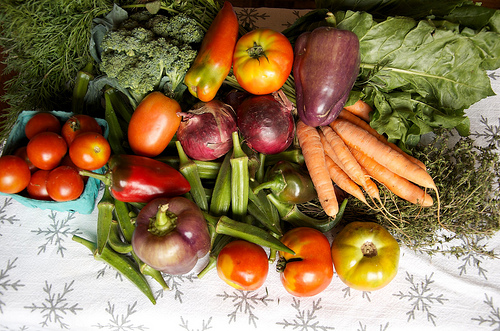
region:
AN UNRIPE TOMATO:
[328, 216, 408, 298]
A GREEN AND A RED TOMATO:
[270, 217, 410, 302]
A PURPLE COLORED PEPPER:
[123, 188, 221, 283]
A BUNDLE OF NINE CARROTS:
[286, 84, 459, 250]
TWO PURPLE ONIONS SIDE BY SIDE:
[166, 87, 306, 166]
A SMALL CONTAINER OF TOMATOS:
[0, 103, 115, 220]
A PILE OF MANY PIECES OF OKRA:
[63, 75, 373, 310]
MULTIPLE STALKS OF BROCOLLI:
[93, 2, 215, 123]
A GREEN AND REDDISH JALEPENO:
[248, 152, 338, 207]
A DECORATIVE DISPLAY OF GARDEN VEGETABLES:
[0, 0, 497, 309]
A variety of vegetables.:
[97, 80, 373, 260]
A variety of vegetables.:
[164, 104, 319, 227]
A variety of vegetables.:
[144, 132, 344, 274]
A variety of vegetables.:
[133, 121, 415, 326]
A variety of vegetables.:
[173, 68, 378, 208]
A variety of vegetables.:
[186, 179, 413, 301]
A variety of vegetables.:
[153, 61, 289, 166]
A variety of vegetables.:
[183, 11, 383, 138]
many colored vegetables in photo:
[14, 10, 456, 328]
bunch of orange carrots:
[294, 128, 434, 216]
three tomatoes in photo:
[224, 212, 405, 306]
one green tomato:
[344, 204, 434, 304]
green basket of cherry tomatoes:
[2, 98, 129, 233]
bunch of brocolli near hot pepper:
[88, 7, 243, 135]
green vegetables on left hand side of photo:
[20, 7, 204, 115]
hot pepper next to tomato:
[182, 7, 303, 111]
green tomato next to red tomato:
[270, 221, 424, 299]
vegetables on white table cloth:
[12, 12, 496, 304]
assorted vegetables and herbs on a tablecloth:
[21, 30, 471, 318]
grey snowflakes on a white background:
[21, 266, 282, 326]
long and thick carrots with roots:
[301, 130, 446, 225]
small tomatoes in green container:
[2, 86, 103, 221]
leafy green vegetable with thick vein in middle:
[367, 16, 488, 136]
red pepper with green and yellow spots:
[176, 15, 236, 100]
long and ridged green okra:
[190, 121, 287, 238]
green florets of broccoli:
[100, 1, 195, 91]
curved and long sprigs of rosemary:
[426, 145, 491, 240]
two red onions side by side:
[175, 100, 305, 156]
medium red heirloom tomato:
[233, 26, 293, 91]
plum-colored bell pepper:
[132, 195, 207, 280]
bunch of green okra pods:
[176, 135, 288, 250]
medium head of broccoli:
[105, 10, 200, 105]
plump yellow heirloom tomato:
[330, 220, 400, 290]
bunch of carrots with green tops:
[296, 117, 436, 217]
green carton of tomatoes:
[0, 110, 105, 212]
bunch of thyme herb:
[421, 130, 496, 256]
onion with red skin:
[177, 102, 239, 157]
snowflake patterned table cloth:
[0, 260, 496, 326]